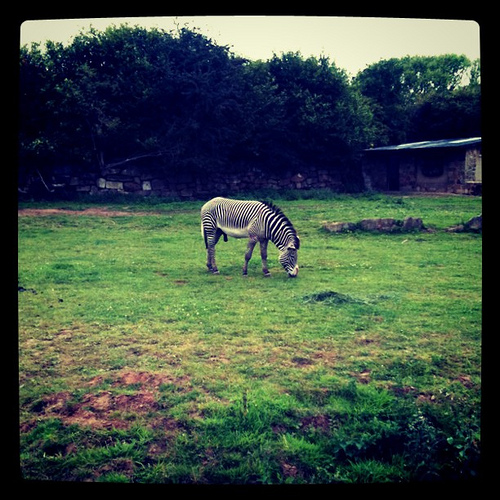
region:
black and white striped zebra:
[200, 197, 296, 275]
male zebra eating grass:
[202, 195, 297, 275]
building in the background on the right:
[370, 135, 485, 195]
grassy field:
[15, 196, 492, 491]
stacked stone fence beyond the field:
[25, 167, 365, 194]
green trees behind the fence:
[20, 26, 480, 157]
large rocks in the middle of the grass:
[327, 215, 479, 235]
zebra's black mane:
[260, 200, 295, 245]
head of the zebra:
[275, 241, 295, 276]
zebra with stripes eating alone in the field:
[198, 195, 298, 276]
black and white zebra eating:
[174, 185, 313, 291]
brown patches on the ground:
[92, 369, 173, 433]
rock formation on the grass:
[315, 200, 451, 255]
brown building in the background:
[357, 134, 490, 199]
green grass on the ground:
[310, 375, 397, 450]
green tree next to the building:
[236, 45, 358, 160]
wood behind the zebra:
[55, 150, 163, 211]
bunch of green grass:
[296, 285, 361, 312]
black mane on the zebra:
[257, 196, 312, 238]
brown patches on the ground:
[145, 256, 195, 299]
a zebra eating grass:
[195, 195, 313, 287]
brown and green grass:
[23, 305, 480, 485]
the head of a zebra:
[280, 243, 299, 280]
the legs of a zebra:
[194, 233, 273, 283]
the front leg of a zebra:
[255, 241, 272, 276]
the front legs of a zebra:
[239, 236, 275, 278]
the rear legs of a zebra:
[196, 233, 224, 276]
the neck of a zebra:
[266, 204, 301, 246]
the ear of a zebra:
[286, 243, 298, 252]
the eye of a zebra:
[288, 255, 295, 265]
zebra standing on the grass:
[180, 188, 317, 290]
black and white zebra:
[187, 192, 309, 281]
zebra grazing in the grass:
[191, 193, 312, 280]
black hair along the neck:
[254, 188, 310, 245]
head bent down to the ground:
[279, 237, 301, 277]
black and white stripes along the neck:
[258, 216, 293, 248]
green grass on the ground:
[22, 199, 479, 482]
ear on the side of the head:
[283, 243, 295, 253]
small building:
[351, 121, 479, 197]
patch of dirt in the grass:
[83, 395, 118, 420]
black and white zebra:
[199, 198, 301, 279]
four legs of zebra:
[199, 229, 271, 277]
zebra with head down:
[203, 194, 302, 273]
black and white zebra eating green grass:
[200, 193, 302, 278]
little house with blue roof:
[366, 130, 483, 191]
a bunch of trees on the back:
[19, 25, 481, 189]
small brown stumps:
[320, 214, 484, 242]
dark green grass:
[10, 194, 482, 480]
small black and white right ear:
[286, 240, 298, 252]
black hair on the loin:
[261, 198, 298, 248]